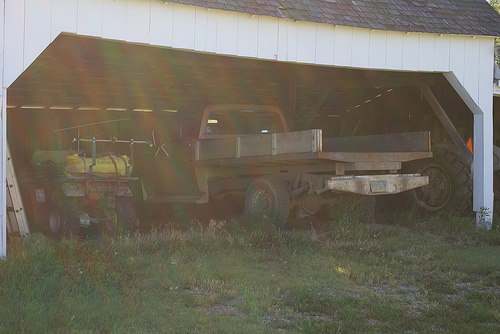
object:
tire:
[399, 140, 473, 218]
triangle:
[465, 136, 475, 156]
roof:
[145, 1, 497, 40]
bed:
[197, 127, 440, 163]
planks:
[40, 7, 476, 74]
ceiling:
[10, 35, 371, 107]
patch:
[330, 265, 352, 279]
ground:
[4, 210, 498, 332]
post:
[472, 109, 495, 233]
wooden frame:
[4, 0, 497, 233]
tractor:
[20, 138, 146, 240]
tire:
[243, 179, 292, 233]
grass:
[2, 217, 498, 332]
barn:
[0, 0, 500, 258]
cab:
[104, 103, 289, 204]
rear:
[204, 109, 284, 134]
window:
[203, 107, 288, 135]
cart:
[128, 103, 438, 233]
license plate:
[371, 179, 389, 192]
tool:
[32, 148, 139, 238]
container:
[64, 148, 135, 177]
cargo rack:
[37, 152, 158, 244]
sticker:
[206, 117, 220, 125]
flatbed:
[195, 127, 435, 173]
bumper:
[312, 170, 430, 197]